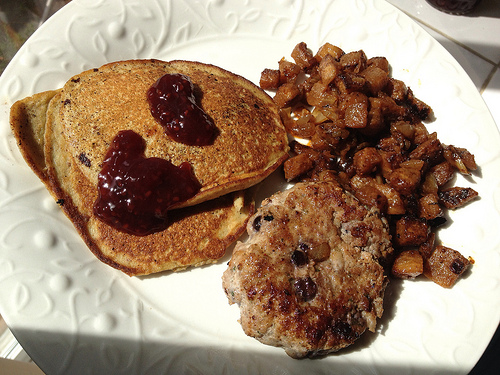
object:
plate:
[0, 0, 499, 373]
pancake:
[53, 54, 295, 212]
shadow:
[3, 328, 449, 374]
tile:
[385, 0, 500, 75]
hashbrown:
[340, 87, 370, 130]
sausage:
[217, 165, 407, 363]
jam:
[143, 71, 227, 150]